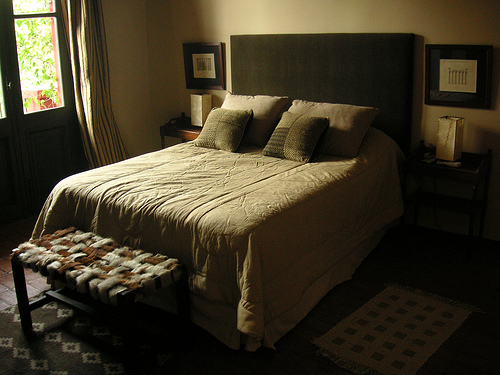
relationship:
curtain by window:
[63, 15, 127, 143] [3, 5, 77, 138]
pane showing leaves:
[12, 14, 72, 115] [16, 25, 55, 87]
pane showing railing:
[12, 14, 72, 115] [50, 2, 64, 97]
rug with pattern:
[1, 293, 140, 373] [43, 324, 97, 361]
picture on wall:
[181, 43, 228, 93] [145, 3, 498, 242]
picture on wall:
[429, 46, 491, 106] [145, 3, 498, 242]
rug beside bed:
[306, 265, 472, 367] [65, 80, 401, 329]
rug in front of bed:
[0, 278, 214, 372] [30, 32, 424, 351]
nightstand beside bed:
[411, 155, 490, 202] [98, 142, 328, 296]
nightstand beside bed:
[158, 116, 206, 145] [98, 142, 328, 296]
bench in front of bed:
[10, 223, 190, 359] [30, 32, 424, 351]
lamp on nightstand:
[177, 82, 224, 130] [156, 111, 216, 148]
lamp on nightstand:
[424, 103, 471, 168] [409, 147, 476, 245]